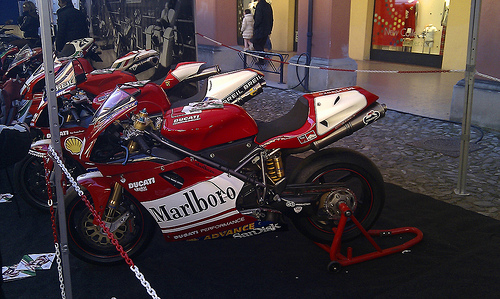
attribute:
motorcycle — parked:
[53, 82, 395, 257]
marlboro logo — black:
[145, 182, 238, 234]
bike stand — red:
[311, 199, 428, 280]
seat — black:
[246, 91, 313, 152]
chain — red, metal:
[27, 158, 138, 272]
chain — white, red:
[37, 142, 161, 298]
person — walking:
[240, 7, 259, 50]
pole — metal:
[451, 2, 484, 199]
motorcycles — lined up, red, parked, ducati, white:
[1, 26, 392, 270]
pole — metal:
[33, 0, 82, 299]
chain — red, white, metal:
[189, 30, 468, 79]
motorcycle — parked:
[11, 55, 272, 214]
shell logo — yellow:
[61, 133, 86, 157]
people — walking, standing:
[15, 1, 105, 60]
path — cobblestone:
[194, 79, 499, 226]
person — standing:
[16, 2, 40, 43]